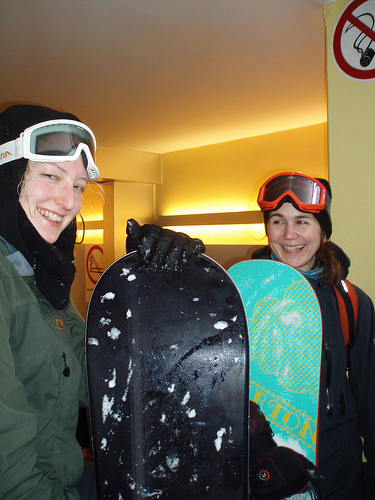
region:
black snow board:
[82, 245, 253, 499]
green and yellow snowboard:
[225, 255, 326, 470]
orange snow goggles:
[253, 169, 329, 215]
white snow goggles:
[0, 116, 100, 183]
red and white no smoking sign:
[82, 241, 108, 304]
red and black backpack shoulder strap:
[330, 275, 361, 358]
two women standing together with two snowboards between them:
[2, 101, 370, 493]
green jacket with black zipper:
[0, 237, 85, 499]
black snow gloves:
[120, 215, 208, 275]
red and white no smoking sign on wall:
[327, 2, 374, 85]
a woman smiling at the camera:
[0, 109, 98, 242]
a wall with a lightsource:
[165, 135, 259, 213]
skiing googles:
[254, 170, 332, 210]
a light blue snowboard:
[238, 256, 321, 498]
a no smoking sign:
[332, 1, 373, 76]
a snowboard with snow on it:
[87, 257, 255, 497]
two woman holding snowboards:
[20, 104, 374, 488]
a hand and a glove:
[109, 217, 214, 275]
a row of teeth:
[36, 207, 65, 223]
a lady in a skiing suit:
[246, 159, 372, 422]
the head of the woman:
[262, 174, 339, 270]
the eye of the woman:
[270, 214, 287, 227]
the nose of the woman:
[283, 214, 299, 242]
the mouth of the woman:
[276, 241, 310, 260]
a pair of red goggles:
[255, 170, 327, 215]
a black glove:
[121, 217, 214, 278]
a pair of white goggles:
[1, 117, 100, 183]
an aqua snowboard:
[223, 255, 321, 480]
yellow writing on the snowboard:
[246, 380, 318, 446]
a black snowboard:
[83, 240, 256, 498]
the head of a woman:
[261, 167, 339, 273]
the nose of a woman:
[282, 222, 301, 243]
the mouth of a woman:
[276, 239, 308, 255]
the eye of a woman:
[293, 216, 311, 228]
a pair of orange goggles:
[253, 170, 335, 209]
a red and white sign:
[81, 236, 115, 306]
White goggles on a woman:
[7, 113, 105, 178]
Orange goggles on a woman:
[254, 170, 342, 226]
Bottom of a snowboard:
[92, 245, 263, 496]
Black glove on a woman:
[118, 212, 213, 276]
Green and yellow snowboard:
[214, 254, 348, 439]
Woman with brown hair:
[237, 169, 373, 289]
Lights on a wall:
[147, 194, 288, 240]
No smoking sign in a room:
[79, 232, 153, 327]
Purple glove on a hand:
[222, 399, 312, 498]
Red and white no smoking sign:
[330, 4, 374, 81]